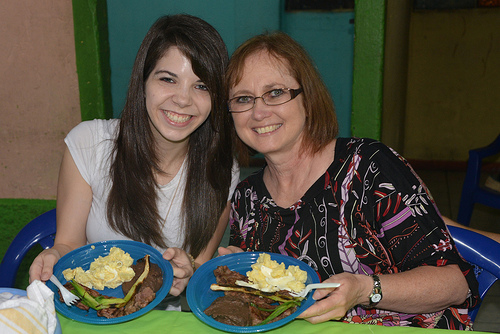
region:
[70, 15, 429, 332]
two people eating food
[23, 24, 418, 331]
two people holding food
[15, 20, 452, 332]
two people holding plates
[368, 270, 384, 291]
black watch strap on hand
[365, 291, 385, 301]
white face of watch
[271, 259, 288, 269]
mashed potatoes on plate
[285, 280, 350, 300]
white plastic fork on plate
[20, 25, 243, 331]
girl holding blue plate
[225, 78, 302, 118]
a woman's eyeglasses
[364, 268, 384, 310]
a woman's watch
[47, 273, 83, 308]
a plastic white fork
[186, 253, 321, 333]
a large blue plate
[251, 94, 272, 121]
the nose of a woman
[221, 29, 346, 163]
a woman's brown hair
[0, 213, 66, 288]
part of a blue chair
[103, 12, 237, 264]
a girl's long hair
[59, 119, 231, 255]
part of a girl's white shirt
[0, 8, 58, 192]
part of a painted wall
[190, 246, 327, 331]
A plate with mostly meat.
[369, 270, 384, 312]
A small, thin wrist watch.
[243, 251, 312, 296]
Mashed potatoes on a plate.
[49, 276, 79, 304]
A white plastic fork.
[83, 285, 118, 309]
Green vegetables on a plate.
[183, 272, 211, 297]
The plate is blue.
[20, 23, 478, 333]
Two women have dinner at a green table.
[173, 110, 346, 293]
this is a mother and daughter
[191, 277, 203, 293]
the plate is plastic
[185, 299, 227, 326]
the plate is blue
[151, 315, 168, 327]
this is a green tablecloth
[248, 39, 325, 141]
these are some glasses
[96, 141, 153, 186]
this is brown hair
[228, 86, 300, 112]
glasses on the woman's face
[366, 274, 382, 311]
watch on woman's wrist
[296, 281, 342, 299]
white fork in hand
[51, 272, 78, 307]
white fork on the plate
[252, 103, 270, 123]
the nose of the woman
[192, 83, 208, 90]
the girl's left eye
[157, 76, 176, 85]
right eye of girl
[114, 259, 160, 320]
steak on the plate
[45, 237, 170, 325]
blue plastic plate in girl's hand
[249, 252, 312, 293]
potato salad on plate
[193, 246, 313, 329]
a plate made for dining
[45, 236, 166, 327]
a plate made for dining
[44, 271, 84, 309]
a utensil made for dining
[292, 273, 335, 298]
a utensil made for dining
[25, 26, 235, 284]
a person is sitting down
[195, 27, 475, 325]
a person is sitting down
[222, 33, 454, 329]
a woman with dark orange hair.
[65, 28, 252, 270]
A woman with dark brown hair.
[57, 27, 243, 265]
A woman with long hair.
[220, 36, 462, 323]
A woman wearing glasses.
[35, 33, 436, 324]
Two people sitting with plates of food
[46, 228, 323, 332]
Round blue plates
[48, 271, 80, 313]
A white plastic fork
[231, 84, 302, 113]
a pair of eyeglasses.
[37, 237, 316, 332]
Plates of food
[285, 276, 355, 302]
a plastic fork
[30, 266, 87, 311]
a plastic fork on the plate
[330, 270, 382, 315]
a whtie plastic fork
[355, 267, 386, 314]
a watch on the wrist